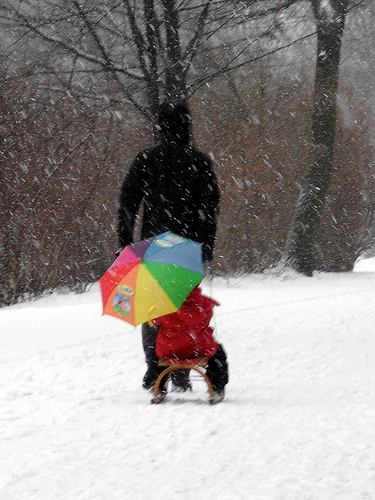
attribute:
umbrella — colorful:
[92, 226, 211, 330]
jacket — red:
[148, 282, 224, 367]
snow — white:
[235, 350, 374, 498]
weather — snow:
[219, 117, 295, 197]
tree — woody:
[48, 8, 313, 91]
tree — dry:
[75, 3, 274, 99]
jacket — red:
[151, 285, 220, 370]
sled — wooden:
[150, 360, 220, 405]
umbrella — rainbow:
[90, 232, 214, 326]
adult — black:
[112, 98, 226, 243]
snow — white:
[219, 415, 306, 465]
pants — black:
[143, 364, 230, 384]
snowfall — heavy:
[32, 90, 349, 215]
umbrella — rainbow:
[99, 228, 216, 321]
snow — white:
[269, 282, 354, 419]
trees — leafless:
[87, 40, 244, 102]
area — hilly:
[227, 251, 372, 329]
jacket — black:
[116, 149, 220, 235]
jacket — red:
[161, 313, 217, 355]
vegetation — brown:
[246, 127, 358, 259]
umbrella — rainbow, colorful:
[98, 228, 206, 322]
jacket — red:
[156, 303, 218, 362]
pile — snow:
[259, 260, 311, 283]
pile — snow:
[309, 267, 337, 278]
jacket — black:
[115, 145, 221, 258]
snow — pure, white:
[1, 249, 373, 497]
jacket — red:
[151, 284, 219, 359]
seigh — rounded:
[150, 353, 227, 404]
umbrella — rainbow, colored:
[98, 231, 209, 327]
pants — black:
[207, 344, 228, 393]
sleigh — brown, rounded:
[151, 358, 226, 405]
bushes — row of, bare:
[2, 57, 371, 304]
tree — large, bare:
[3, 1, 320, 125]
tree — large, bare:
[260, 2, 373, 279]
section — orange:
[104, 261, 141, 325]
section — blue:
[142, 227, 203, 258]